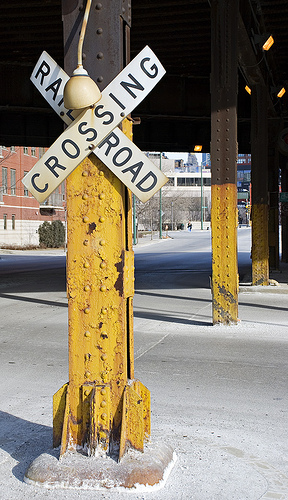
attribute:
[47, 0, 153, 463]
pole — metal, yellow, steel, in a row, for support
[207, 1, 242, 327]
pole — metal, yellow, steel, in a row, for support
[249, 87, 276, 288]
pole — metal, yellow, steel, in a row, for support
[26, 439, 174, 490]
base — cement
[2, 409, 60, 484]
shadow — on the ground, on ground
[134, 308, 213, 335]
shadow — on the ground, on ground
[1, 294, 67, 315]
shadow — on the ground, on ground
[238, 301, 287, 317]
shadow — on the ground, on ground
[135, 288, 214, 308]
shadow — on the ground, on ground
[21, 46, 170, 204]
sign — railroad crossing, white, black, railroad xing sign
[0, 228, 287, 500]
street — gray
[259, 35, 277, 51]
lamp — hanging, illuminated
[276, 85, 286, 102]
lamp — hanging, illuminated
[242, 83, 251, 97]
lamp — hanging, illuminated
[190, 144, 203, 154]
lamp — hanging, illuminated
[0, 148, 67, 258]
building — red, brick, partly white, in background, gray, cement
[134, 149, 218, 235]
building — in background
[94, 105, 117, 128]
letter — black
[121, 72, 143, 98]
letter — black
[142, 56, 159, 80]
letter — black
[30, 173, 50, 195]
letter — black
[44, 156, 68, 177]
letter — black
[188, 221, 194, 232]
person — walking, in background, wearing jeans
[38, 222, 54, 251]
bush — green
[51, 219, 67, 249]
bush — green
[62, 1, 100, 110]
light — white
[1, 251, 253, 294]
shadow — on ground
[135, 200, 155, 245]
tree — in background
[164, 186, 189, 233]
tree — in background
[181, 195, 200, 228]
tree — in background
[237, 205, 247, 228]
tree — in background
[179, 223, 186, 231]
person — in background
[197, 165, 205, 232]
post — green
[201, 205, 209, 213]
street sign — green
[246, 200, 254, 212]
traffic light — in distance